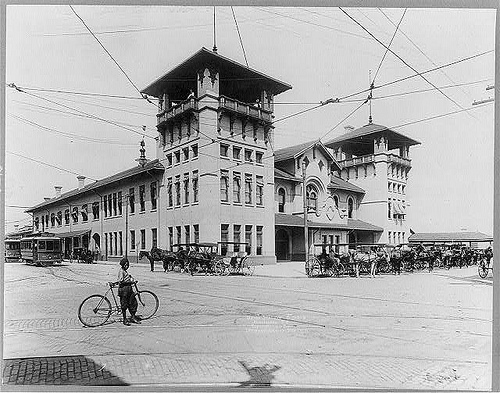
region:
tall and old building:
[75, 74, 321, 321]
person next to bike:
[80, 243, 177, 331]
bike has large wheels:
[79, 261, 171, 347]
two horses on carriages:
[131, 231, 257, 270]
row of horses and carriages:
[290, 230, 497, 266]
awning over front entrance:
[271, 221, 388, 242]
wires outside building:
[3, 20, 458, 136]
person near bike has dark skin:
[103, 253, 149, 331]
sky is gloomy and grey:
[5, 13, 122, 150]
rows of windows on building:
[90, 190, 222, 275]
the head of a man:
[118, 252, 135, 269]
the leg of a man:
[116, 289, 132, 318]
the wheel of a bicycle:
[75, 291, 113, 330]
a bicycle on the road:
[73, 273, 160, 329]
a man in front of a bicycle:
[111, 251, 142, 329]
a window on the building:
[215, 167, 232, 207]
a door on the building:
[274, 225, 293, 262]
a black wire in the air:
[68, 2, 145, 95]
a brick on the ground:
[31, 365, 41, 377]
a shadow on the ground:
[1, 352, 129, 389]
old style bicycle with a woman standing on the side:
[84, 248, 160, 322]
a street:
[253, 262, 332, 354]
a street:
[248, 332, 292, 384]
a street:
[281, 282, 383, 376]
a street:
[243, 260, 409, 391]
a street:
[422, 351, 454, 388]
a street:
[288, 216, 401, 336]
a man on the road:
[116, 254, 146, 330]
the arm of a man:
[113, 270, 138, 286]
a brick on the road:
[46, 357, 56, 373]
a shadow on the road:
[2, 348, 131, 388]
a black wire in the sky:
[66, 4, 161, 109]